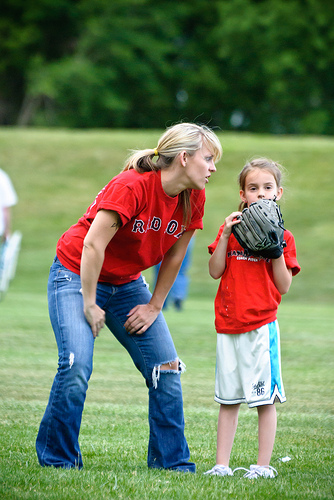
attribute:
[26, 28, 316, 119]
branches — drooping, curved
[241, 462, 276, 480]
tennis shoe — tennis ,  lace 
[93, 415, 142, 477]
grass — bright green, healthy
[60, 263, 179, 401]
pants — blue, torn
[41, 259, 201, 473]
jeans — blue, woman's 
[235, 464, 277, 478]
tennis shoe — girl's tennis 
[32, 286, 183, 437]
jeans — blue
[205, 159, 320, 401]
girl — staring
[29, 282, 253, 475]
legs — wide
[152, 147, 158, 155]
hairband — yellow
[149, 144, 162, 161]
band — yellow elastic 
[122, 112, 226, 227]
hair — woman's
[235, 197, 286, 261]
glove — girl's baseball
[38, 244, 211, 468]
pants — denim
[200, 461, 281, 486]
shoes — white 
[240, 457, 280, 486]
tennis shoe — white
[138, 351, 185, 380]
knee — ripped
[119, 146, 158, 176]
ponytail — woman's blonde 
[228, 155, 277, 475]
girl — white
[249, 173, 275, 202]
look — dreamy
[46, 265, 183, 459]
pants — blue